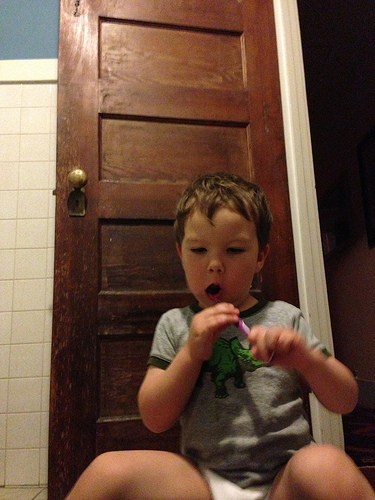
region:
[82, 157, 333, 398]
little kid in front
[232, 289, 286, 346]
hand holding a purple brush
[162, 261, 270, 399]
tooth brush in kids mouth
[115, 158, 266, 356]
open mouth of little kid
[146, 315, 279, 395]
dinosaur of little kid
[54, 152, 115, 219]
golden door knob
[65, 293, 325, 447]
small grey t-shirt on kid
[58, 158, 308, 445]
kid brushing his teeth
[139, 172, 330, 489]
little kid sitting on floor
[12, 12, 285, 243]
large wooden door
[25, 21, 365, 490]
the door is wooden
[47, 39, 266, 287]
the door is wooden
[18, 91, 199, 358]
the door is wooden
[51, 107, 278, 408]
the door is wooden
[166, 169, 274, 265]
the kid has brown hair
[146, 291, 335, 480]
the kid is wearing a grey shirt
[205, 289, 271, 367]
the kid is brushing his teeth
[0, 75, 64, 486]
the tile is on the wall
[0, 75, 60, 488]
the tile on the wall is white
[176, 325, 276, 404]
the kid has a dinosaur on his shirt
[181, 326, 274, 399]
the dinosaur is green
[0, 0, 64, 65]
the top of the wall is blue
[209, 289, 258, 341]
the toothbrush is pink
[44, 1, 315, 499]
the door is wood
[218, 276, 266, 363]
he is brushing his teeth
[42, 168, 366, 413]
he is in the bathroom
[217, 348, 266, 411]
he has a dinasour on his shirt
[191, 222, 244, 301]
he has a cute face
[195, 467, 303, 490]
he is not wearing pants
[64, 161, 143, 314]
the door is open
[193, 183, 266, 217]
he has brown hair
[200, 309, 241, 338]
he has little fingers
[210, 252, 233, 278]
he has a cute nose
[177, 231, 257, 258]
his eyes are wide open